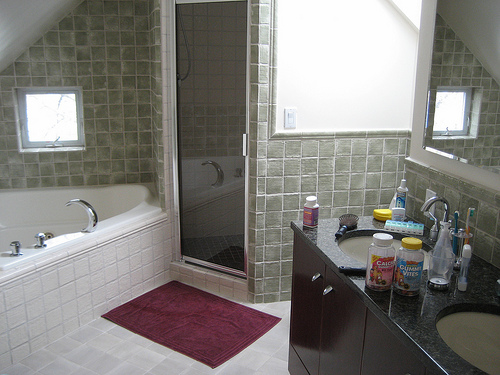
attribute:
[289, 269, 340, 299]
knobs — several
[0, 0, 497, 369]
bathroom — nice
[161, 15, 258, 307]
door — glass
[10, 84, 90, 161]
window — interior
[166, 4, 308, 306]
shower — enclosed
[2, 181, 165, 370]
tub — bath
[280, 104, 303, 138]
outlet — electric 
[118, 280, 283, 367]
mat — red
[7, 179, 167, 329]
tub — white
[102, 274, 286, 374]
rug — small, red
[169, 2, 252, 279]
shower door — bathroom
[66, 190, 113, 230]
faucet — large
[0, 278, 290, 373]
floor — tile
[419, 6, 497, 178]
mirror — wall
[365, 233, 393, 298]
bottle — small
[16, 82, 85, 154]
window — clear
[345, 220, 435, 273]
sink — personal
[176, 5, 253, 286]
door — bathroom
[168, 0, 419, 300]
shower — bathroom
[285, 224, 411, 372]
cabinet — nearby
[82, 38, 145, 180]
wall — painted 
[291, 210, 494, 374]
counter — bathroom, nearby, cluttered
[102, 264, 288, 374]
rug — maroon, bath rug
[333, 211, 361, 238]
hair brush — nice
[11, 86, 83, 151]
window — large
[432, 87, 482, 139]
window — clear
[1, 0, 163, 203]
wall — tile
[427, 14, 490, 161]
wall — clean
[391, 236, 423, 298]
jar — ceramic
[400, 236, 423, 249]
top — metal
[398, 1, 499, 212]
mirror — large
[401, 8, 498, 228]
wall — nearby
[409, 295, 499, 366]
cabinet — nice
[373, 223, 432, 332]
label — interesting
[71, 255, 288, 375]
floor — clean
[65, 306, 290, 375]
floor — clean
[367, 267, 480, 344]
vanity — nearby